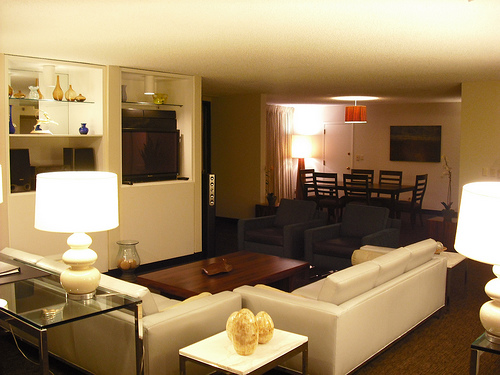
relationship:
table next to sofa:
[137, 249, 307, 296] [230, 237, 448, 374]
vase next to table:
[114, 238, 141, 280] [137, 249, 307, 296]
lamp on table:
[34, 169, 121, 301] [3, 253, 146, 374]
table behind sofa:
[3, 253, 146, 374] [0, 246, 243, 374]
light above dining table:
[343, 99, 367, 124] [309, 179, 414, 206]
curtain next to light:
[265, 104, 294, 203] [288, 131, 315, 198]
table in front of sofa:
[137, 249, 307, 296] [230, 237, 448, 374]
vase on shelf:
[78, 123, 89, 135] [9, 132, 103, 140]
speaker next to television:
[202, 172, 218, 259] [121, 127, 182, 183]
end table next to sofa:
[179, 321, 310, 374] [230, 237, 448, 374]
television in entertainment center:
[121, 127, 182, 183] [119, 70, 195, 186]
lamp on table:
[454, 179, 498, 343] [468, 330, 499, 374]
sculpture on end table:
[225, 307, 274, 357] [179, 321, 310, 374]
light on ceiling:
[343, 99, 367, 124] [267, 96, 464, 108]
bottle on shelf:
[8, 103, 16, 134] [9, 132, 103, 140]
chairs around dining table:
[311, 172, 374, 211] [309, 179, 414, 206]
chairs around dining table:
[351, 166, 429, 228] [309, 179, 414, 206]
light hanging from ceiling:
[343, 99, 367, 124] [267, 96, 464, 108]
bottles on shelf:
[9, 72, 88, 101] [7, 96, 98, 106]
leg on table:
[134, 301, 145, 374] [3, 253, 146, 374]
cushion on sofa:
[318, 262, 381, 302] [230, 237, 448, 374]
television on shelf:
[121, 127, 182, 183] [122, 177, 194, 190]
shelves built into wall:
[8, 92, 105, 142] [2, 53, 201, 267]